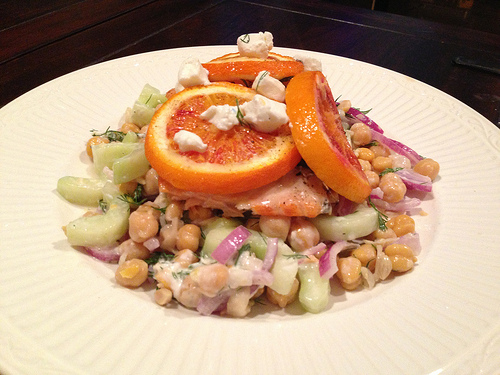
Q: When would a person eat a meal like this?
A: During a diet.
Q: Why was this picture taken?
A: For healthy decisions.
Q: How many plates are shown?
A: One.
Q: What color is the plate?
A: White.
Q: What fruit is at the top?
A: An orange.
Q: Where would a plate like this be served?
A: A restaurant.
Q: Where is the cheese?
A: At the top.